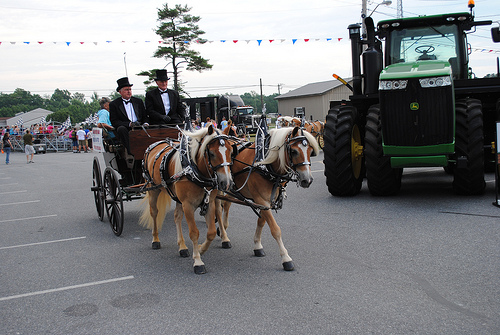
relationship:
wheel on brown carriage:
[89, 153, 105, 220] [90, 122, 202, 236]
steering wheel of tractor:
[411, 44, 435, 54] [317, 14, 499, 199]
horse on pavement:
[138, 121, 236, 275] [0, 150, 499, 333]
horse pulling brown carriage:
[138, 121, 236, 275] [90, 122, 202, 236]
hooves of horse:
[209, 223, 295, 272] [145, 129, 236, 272]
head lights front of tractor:
[377, 77, 451, 90] [317, 14, 499, 199]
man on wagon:
[109, 77, 150, 177] [84, 119, 216, 239]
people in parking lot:
[19, 129, 40, 162] [2, 111, 494, 330]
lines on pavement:
[3, 188, 138, 323] [9, 155, 487, 273]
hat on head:
[116, 77, 133, 92] [117, 84, 134, 98]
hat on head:
[150, 69, 172, 81] [156, 78, 168, 90]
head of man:
[117, 84, 134, 98] [111, 78, 151, 174]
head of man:
[156, 78, 168, 90] [145, 69, 185, 131]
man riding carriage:
[147, 69, 185, 126] [84, 121, 207, 238]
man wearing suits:
[109, 77, 150, 177] [149, 91, 176, 116]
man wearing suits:
[147, 69, 185, 126] [109, 99, 143, 128]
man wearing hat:
[147, 69, 185, 126] [152, 70, 170, 80]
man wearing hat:
[147, 69, 185, 126] [131, 43, 181, 83]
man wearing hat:
[109, 77, 150, 177] [114, 74, 131, 94]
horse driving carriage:
[138, 121, 236, 275] [58, 123, 152, 218]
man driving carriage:
[109, 77, 150, 177] [89, 118, 215, 234]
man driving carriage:
[147, 69, 185, 126] [89, 118, 215, 234]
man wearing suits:
[109, 77, 152, 177] [109, 95, 150, 128]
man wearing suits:
[147, 69, 185, 126] [145, 87, 189, 124]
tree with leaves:
[129, 2, 219, 87] [153, 0, 183, 18]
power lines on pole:
[7, 82, 295, 92] [255, 75, 265, 113]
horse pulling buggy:
[139, 122, 236, 277] [85, 123, 188, 245]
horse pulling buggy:
[216, 126, 318, 271] [85, 123, 188, 245]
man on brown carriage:
[147, 69, 185, 126] [90, 122, 202, 236]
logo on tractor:
[408, 100, 420, 112] [317, 14, 499, 199]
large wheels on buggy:
[102, 165, 123, 237] [89, 117, 188, 237]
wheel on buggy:
[89, 153, 105, 220] [89, 117, 188, 237]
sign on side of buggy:
[78, 122, 120, 171] [86, 121, 206, 236]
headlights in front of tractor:
[377, 65, 462, 99] [324, 0, 500, 198]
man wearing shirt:
[89, 89, 120, 159] [92, 110, 117, 143]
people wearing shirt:
[2, 132, 13, 165] [1, 135, 12, 145]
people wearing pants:
[2, 132, 13, 165] [1, 143, 11, 171]